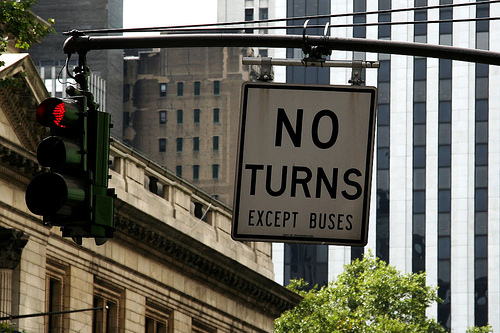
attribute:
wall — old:
[4, 185, 280, 332]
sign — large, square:
[231, 77, 376, 247]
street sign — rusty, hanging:
[222, 80, 389, 249]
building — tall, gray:
[9, 2, 124, 150]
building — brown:
[124, 23, 260, 242]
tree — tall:
[1, 4, 53, 52]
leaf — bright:
[396, 281, 408, 294]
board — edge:
[227, 71, 379, 255]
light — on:
[53, 100, 67, 127]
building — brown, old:
[130, 19, 270, 214]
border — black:
[197, 91, 397, 253]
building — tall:
[0, 50, 302, 332]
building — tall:
[275, 3, 497, 330]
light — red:
[18, 75, 142, 229]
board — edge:
[178, 62, 391, 281]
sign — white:
[196, 45, 414, 259]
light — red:
[31, 92, 84, 138]